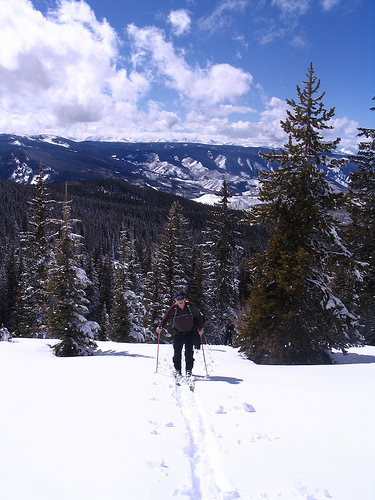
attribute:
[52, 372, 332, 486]
snow — white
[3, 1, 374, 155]
clouds — white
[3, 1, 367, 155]
sky — blue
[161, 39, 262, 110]
clouds — white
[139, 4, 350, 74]
sky — blue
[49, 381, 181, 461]
snow — white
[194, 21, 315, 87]
clouds — white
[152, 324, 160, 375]
pole — long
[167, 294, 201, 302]
hat — black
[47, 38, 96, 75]
clouds — white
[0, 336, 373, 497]
snow — white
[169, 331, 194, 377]
pants — black, snow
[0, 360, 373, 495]
snow — white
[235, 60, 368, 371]
tree — tall, green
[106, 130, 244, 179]
mountains — distant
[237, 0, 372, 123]
blue sky — clear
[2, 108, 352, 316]
snowy forest — endless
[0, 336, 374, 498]
hill — snowy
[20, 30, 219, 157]
clouds — white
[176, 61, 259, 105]
cow — white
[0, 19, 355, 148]
sky — blue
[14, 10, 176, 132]
clouds — white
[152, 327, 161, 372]
ski pole — red, black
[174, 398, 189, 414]
track — fresh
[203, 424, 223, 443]
track — fresh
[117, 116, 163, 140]
cloud — soft